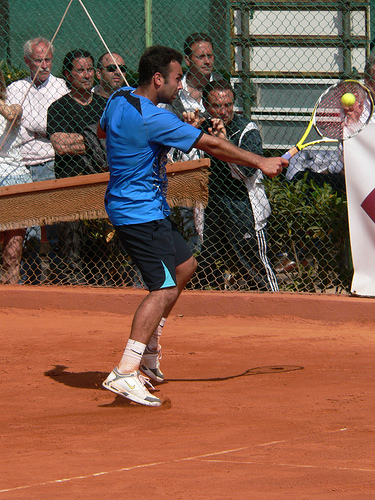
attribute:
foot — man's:
[99, 363, 163, 406]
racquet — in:
[279, 78, 371, 165]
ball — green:
[339, 90, 355, 109]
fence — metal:
[2, 0, 370, 301]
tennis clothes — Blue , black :
[97, 87, 204, 290]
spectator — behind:
[6, 36, 71, 183]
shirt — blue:
[95, 84, 204, 228]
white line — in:
[2, 423, 371, 492]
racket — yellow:
[266, 79, 374, 180]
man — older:
[34, 66, 52, 72]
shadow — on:
[36, 342, 323, 429]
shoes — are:
[114, 336, 178, 462]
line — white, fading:
[1, 421, 372, 496]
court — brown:
[56, 302, 294, 480]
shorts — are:
[120, 204, 207, 289]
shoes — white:
[100, 350, 169, 407]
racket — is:
[278, 77, 372, 162]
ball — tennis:
[340, 92, 356, 108]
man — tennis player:
[82, 45, 238, 298]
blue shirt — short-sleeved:
[103, 90, 182, 220]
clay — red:
[113, 421, 239, 491]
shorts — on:
[125, 262, 183, 292]